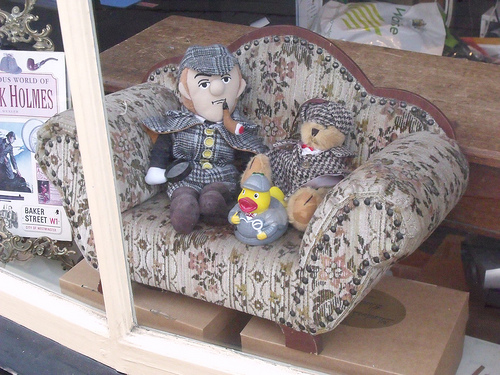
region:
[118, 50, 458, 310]
floral printed toy couch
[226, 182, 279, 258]
a detective rubber ducky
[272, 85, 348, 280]
sherlock homes bear with hat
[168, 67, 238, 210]
sherlock holmes with pipe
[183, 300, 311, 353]
two cardboard boxes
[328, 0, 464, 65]
a plastic bag with green design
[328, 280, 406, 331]
gold colored oval sticker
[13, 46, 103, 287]
a sherlock holmes book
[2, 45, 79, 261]
silver colored book holder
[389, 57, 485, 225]
large dark wood desk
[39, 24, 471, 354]
dolls in a small upholstered chair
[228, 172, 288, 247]
yellow toy duck in a deerstalker hat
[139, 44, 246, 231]
doll on left dressed like Sherlock Holmes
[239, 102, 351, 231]
teddy bear dressed in houndstooth jacket and hat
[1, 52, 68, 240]
sign on window to the left of the chair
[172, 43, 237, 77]
deerstalker hat the doll on the left is wearing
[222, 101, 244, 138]
pipe in mouth of the doll on the left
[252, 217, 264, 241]
tiny white magnifying glass the toy duck is holding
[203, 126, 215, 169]
buttons on the coat of the doll on the left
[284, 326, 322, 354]
right brown foot of the small upholstered chair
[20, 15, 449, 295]
picture of a toy couch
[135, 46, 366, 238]
stuffed animals on the couch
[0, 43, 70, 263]
this is an advertisement for the stuffed toy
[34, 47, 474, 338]
the couch is on a wooden platform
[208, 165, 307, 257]
this is a rubber ducky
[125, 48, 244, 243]
this toy is Sherlock Holmes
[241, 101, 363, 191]
This Teddy Bear is Dr. Watson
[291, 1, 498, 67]
this is clutter in the background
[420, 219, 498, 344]
this is an item on the side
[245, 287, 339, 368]
this is a wooden leg on the couch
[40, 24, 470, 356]
a small toy couch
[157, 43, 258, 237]
a Sherlock Holmes doll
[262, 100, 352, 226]
a detective plush teddy bear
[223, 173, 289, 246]
a detective rubber duck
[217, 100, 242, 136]
a felt toy pipe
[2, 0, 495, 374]
a store front window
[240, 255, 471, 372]
a large cardboard box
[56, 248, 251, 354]
a large cardboard box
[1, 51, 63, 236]
a Sherlock Holmes advertisement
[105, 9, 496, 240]
a long wooden table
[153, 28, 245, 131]
This is a ted bear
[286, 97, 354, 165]
This is a ted bear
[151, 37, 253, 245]
This is a ted bear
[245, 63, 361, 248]
This is a ted bear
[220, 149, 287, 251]
This is a ted bear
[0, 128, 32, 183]
This is a ted bear